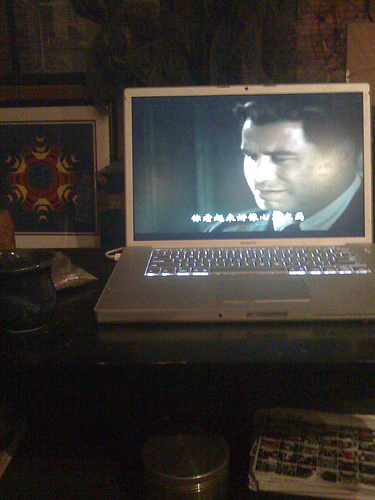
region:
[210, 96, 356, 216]
face of the person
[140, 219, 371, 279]
key board of the laptop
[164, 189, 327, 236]
a text in the screen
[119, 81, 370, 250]
monitor of the laptop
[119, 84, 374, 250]
a screen of the laptop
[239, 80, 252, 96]
front camera of laptop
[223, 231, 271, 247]
name of the laptop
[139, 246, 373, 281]
key board illuminate with white light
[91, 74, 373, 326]
silver plastic lap top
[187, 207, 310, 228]
asian movie sub titles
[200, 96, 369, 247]
man in a suit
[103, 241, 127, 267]
white USB cord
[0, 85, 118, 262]
framed abstract art print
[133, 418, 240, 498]
shiny silver metal cylinder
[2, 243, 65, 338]
small blue ceramic dish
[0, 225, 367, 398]
dark wooden computer desk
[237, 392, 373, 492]
small pictures printed in a grid pattern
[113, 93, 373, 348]
grey laptop on table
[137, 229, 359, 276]
grey keyboard on laptop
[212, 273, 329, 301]
grey touchpad on laptop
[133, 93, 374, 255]
white frame on monitor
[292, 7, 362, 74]
brick wall behind monitor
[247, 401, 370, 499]
white paper under laptop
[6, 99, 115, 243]
picture frame near laptop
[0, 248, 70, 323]
small cup near laptop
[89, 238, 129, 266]
white power plug in laptop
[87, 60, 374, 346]
a macbook pro is open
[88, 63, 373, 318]
the computer is on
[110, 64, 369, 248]
there is a movie on the screen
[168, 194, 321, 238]
these are subtitles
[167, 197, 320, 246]
there are Chinese subtitles on the screen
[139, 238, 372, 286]
the keyboard is lit up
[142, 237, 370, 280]
the keyboard is illuminated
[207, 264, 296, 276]
this is the spacebar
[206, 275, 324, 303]
this is the trackpad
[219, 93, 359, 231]
John Travolta is in the onscreen movie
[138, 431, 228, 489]
a silver container with lid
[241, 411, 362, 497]
printouts of picture comps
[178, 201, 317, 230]
subtitles on the screen in chinese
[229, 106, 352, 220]
a very serious man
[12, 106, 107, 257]
a framed painting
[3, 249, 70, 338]
a blue ceramic vase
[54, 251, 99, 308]
a plastic bag full of something green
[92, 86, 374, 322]
an Apple MacBook Pro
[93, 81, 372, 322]
an open laptop computer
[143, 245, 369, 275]
a backlit computer keyboard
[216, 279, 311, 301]
a computer track pad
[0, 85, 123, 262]
a framed graphic print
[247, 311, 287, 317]
a lid release button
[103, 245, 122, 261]
a computer power cable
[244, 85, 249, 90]
an Apple iSight camera hole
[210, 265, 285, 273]
a computer spacebar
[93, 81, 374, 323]
large silver small laptop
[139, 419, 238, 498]
small round disc case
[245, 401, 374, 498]
large white paper book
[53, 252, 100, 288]
small plastic clear bag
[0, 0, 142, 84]
large colored picture painting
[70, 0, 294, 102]
large wide green drapes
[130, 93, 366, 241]
large wide square screen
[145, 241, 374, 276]
large wide lit keyboard